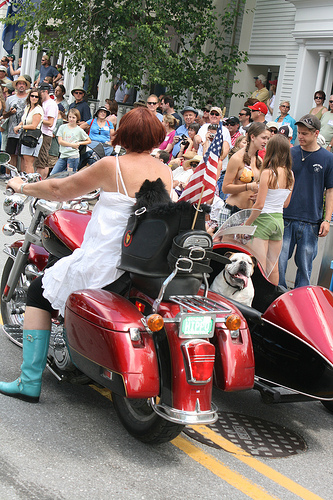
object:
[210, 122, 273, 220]
girl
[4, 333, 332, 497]
street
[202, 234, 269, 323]
bulldog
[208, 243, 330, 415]
sidecar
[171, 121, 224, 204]
flag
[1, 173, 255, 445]
motorcycle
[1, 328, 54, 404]
boot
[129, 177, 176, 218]
cat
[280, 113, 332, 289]
man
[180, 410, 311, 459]
man hole cover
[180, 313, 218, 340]
license plate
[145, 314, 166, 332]
brake light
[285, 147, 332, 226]
t-shirt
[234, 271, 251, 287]
tongue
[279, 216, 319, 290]
jeans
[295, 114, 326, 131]
hat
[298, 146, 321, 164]
neck chain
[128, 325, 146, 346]
turn signal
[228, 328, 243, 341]
right turn signal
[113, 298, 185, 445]
tire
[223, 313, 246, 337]
tail light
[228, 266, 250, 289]
mouth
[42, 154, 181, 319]
dress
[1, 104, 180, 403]
lady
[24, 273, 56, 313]
leggings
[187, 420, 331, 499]
line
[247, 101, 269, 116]
hat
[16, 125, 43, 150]
handbag`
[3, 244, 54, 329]
wheel